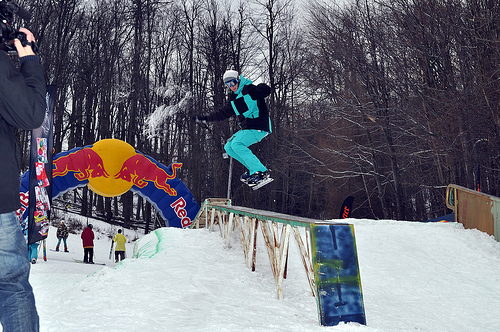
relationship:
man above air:
[192, 69, 279, 190] [214, 188, 297, 217]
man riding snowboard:
[192, 69, 279, 190] [240, 170, 275, 190]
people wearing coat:
[111, 228, 127, 262] [107, 234, 127, 252]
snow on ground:
[17, 217, 497, 329] [33, 215, 498, 330]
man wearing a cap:
[188, 50, 304, 209] [220, 70, 243, 86]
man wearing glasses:
[192, 69, 279, 190] [221, 78, 238, 90]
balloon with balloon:
[45, 147, 205, 207] [45, 147, 205, 207]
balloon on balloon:
[45, 147, 205, 207] [45, 147, 205, 207]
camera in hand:
[0, 0, 41, 55] [4, 26, 39, 54]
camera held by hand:
[0, 0, 41, 55] [4, 26, 39, 54]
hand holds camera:
[4, 26, 39, 54] [0, 0, 41, 55]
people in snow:
[80, 223, 95, 262] [17, 217, 497, 329]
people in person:
[80, 223, 95, 262] [112, 228, 127, 260]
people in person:
[80, 223, 95, 262] [53, 217, 71, 252]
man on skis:
[192, 69, 279, 190] [110, 237, 114, 263]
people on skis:
[79, 211, 95, 262] [110, 237, 114, 263]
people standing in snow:
[55, 220, 67, 255] [17, 217, 497, 329]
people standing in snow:
[80, 223, 95, 262] [17, 217, 497, 329]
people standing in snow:
[111, 228, 127, 262] [17, 217, 497, 329]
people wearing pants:
[80, 223, 95, 262] [81, 245, 98, 262]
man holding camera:
[0, 0, 53, 330] [0, 0, 41, 55]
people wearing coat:
[80, 223, 95, 262] [81, 226, 96, 246]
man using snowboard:
[192, 69, 279, 190] [214, 175, 287, 193]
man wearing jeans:
[0, 0, 53, 330] [0, 212, 42, 329]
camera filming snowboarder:
[0, 0, 41, 55] [190, 68, 282, 190]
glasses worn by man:
[218, 78, 238, 90] [192, 69, 279, 190]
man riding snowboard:
[192, 69, 279, 190] [214, 175, 287, 193]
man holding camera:
[0, 0, 53, 330] [0, 11, 39, 54]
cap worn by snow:
[218, 64, 243, 86] [361, 217, 482, 330]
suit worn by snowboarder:
[201, 64, 281, 194] [205, 58, 286, 193]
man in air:
[192, 69, 279, 190] [10, 0, 493, 320]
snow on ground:
[96, 225, 230, 327] [34, 225, 313, 330]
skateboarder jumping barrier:
[148, 31, 328, 273] [202, 193, 368, 330]